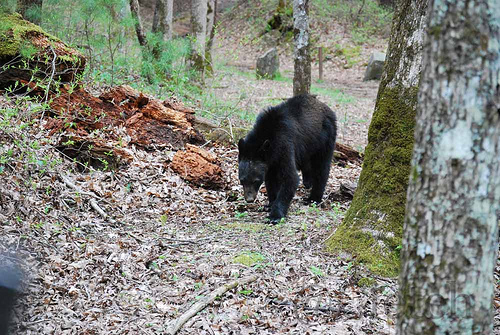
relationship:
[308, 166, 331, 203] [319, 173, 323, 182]
leg covered in black fur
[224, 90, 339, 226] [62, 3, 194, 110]
bear walking in woods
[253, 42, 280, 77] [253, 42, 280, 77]
stump of stump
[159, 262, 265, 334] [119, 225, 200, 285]
stick across ground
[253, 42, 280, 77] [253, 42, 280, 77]
trunk of a stump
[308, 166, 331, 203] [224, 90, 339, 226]
leg of a bear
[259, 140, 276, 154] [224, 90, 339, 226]
ear of a bear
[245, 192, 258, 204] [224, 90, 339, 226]
nose of a bear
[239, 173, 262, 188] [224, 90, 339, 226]
eyes of a bear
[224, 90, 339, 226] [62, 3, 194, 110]
bear in woods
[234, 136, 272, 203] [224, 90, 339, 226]
head of a bear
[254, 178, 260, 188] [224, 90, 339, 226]
eye of a bear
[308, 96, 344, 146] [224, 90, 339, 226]
rear of a bear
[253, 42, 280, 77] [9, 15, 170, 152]
trunk of a tree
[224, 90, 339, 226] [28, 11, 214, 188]
bear in a forest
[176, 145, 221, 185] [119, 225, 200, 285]
wood across ground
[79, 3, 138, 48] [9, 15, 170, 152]
vines growing on tree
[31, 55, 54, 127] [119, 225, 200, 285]
branch across ground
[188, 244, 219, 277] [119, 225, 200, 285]
leaves across ground